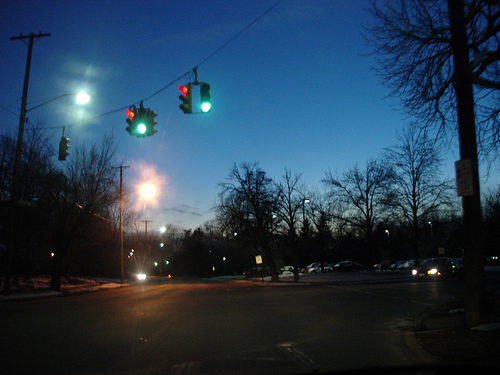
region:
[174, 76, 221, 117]
street light on wire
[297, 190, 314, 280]
light on a pole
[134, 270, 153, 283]
head lights of a car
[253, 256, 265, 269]
sign on a pole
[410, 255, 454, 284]
car with lights on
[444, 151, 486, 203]
sign on a tree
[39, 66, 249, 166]
stop lights on a cable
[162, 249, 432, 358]
a fork in the road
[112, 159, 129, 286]
a telephone pole along a street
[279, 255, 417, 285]
car parking lot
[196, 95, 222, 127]
green light lit up on right signal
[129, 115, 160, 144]
green lit up signal on left device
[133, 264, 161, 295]
two car headlights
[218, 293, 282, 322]
dark road in the intersection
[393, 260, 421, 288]
right lit up headlight of car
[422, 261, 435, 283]
left lit up car headligh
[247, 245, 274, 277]
white sign in the distance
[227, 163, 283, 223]
bare tree with no leaves in center of photo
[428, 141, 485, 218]
red and white sign next to tree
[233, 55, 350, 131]
blue sky to right of street signals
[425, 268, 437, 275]
lights on the car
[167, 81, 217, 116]
traffic lights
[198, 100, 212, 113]
a green light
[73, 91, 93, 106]
the moon in the sky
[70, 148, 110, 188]
tree branches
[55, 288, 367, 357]
the street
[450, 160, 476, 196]
a street sign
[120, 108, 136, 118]
a red traffic light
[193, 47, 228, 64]
an electrical line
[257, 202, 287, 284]
a tree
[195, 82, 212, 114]
an electric traffic signal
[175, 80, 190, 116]
an electric traffic signal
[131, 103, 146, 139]
an electric traffic signal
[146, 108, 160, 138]
an electric traffic signal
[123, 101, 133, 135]
an electric traffic signal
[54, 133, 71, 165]
an electric traffic signal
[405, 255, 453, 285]
car with headlights on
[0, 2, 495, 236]
dark blue night sky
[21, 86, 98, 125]
an overhead street light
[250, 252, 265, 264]
a white road sign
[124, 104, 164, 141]
A stoplight with a green and red light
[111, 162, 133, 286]
A power pole holding wires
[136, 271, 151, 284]
Two car lights are on.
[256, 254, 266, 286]
A sign stands on the corner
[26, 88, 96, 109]
A streetlamp is on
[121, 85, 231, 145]
Two hanging stop lights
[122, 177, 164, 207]
The glow of a street lamp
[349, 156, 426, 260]
Two trees stand together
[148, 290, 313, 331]
An empty segment of road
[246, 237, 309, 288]
Two trees on a curb